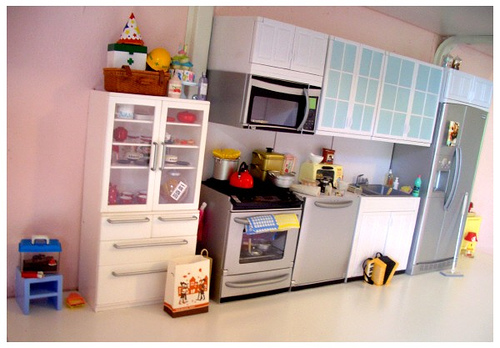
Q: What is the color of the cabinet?
A: White.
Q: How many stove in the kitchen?
A: One.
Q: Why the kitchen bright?
A: It's morning.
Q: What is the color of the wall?
A: Pink.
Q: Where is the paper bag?
A: In front of the cabinet.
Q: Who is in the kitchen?
A: No one.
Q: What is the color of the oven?
A: Silver.